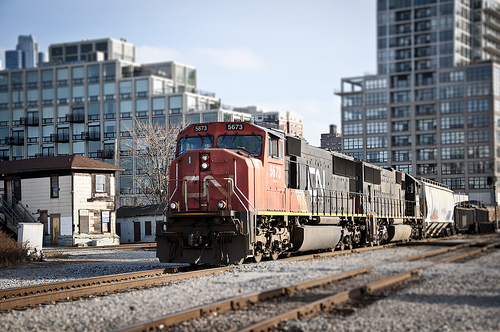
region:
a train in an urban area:
[9, 9, 485, 327]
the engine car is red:
[151, 84, 404, 276]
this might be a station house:
[7, 136, 152, 275]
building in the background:
[1, 28, 293, 262]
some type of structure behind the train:
[316, 0, 496, 245]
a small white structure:
[118, 193, 280, 263]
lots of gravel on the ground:
[4, 240, 496, 330]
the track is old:
[86, 258, 478, 329]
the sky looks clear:
[3, 5, 468, 135]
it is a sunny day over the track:
[13, 13, 496, 281]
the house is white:
[23, 138, 143, 286]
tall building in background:
[372, 2, 484, 157]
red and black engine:
[158, 120, 415, 253]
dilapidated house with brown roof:
[2, 152, 127, 264]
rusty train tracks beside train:
[198, 237, 490, 299]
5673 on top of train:
[223, 121, 245, 131]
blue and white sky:
[215, 12, 332, 76]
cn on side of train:
[305, 163, 332, 200]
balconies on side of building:
[12, 110, 114, 143]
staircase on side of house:
[1, 190, 39, 245]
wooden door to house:
[49, 210, 61, 245]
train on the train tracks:
[138, 96, 483, 275]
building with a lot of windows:
[316, 1, 498, 221]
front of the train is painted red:
[162, 110, 306, 275]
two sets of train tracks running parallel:
[1, 253, 423, 328]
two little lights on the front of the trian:
[199, 151, 211, 171]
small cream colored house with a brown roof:
[8, 148, 136, 258]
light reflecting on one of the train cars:
[422, 182, 462, 219]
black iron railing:
[306, 185, 368, 216]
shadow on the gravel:
[401, 288, 499, 321]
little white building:
[109, 204, 173, 239]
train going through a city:
[151, 106, 489, 271]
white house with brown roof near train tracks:
[1, 149, 123, 250]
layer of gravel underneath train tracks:
[0, 221, 499, 329]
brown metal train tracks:
[0, 227, 499, 329]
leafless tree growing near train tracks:
[112, 108, 193, 269]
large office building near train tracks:
[1, 36, 301, 251]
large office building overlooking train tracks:
[335, 16, 498, 238]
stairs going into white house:
[1, 197, 53, 252]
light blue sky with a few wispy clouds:
[0, 0, 407, 170]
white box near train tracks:
[12, 218, 45, 264]